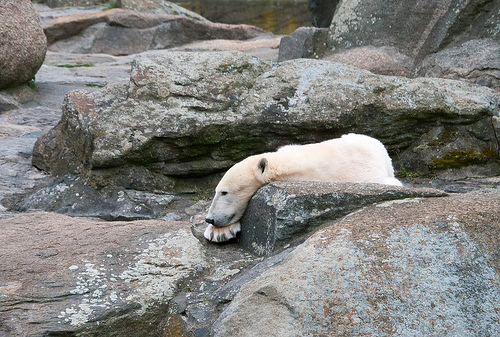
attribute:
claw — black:
[218, 227, 230, 243]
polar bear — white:
[188, 96, 409, 249]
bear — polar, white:
[202, 112, 444, 259]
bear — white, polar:
[212, 120, 404, 215]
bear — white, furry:
[198, 133, 393, 245]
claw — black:
[206, 228, 216, 245]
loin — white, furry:
[296, 139, 371, 180]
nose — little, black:
[201, 209, 218, 226]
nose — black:
[201, 214, 215, 226]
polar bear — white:
[196, 128, 414, 248]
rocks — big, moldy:
[3, 0, 493, 335]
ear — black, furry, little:
[247, 150, 278, 177]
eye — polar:
[221, 189, 229, 196]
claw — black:
[208, 232, 215, 241]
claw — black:
[215, 234, 220, 245]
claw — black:
[222, 233, 227, 243]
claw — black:
[231, 229, 238, 239]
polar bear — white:
[204, 132, 403, 243]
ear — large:
[255, 157, 270, 184]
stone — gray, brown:
[249, 210, 474, 321]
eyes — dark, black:
[203, 184, 231, 204]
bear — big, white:
[203, 136, 400, 242]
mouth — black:
[209, 213, 240, 228]